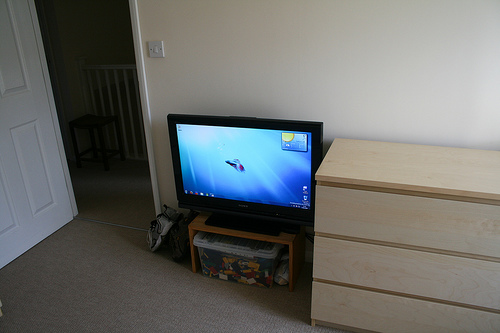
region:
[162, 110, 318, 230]
a flat screen tv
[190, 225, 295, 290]
container full of legos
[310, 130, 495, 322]
a tan three drawer dresser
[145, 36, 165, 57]
a white light switch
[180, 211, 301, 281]
a wood tv stand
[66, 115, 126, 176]
a little stool in hallway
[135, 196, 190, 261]
two pair of tennis shoes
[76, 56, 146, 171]
a white railing in hallway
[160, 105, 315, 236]
a tv with the screen on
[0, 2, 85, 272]
a white bedroom door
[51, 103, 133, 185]
small stole sitting outside the room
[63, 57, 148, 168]
Railing outside the room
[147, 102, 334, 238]
television that is switched on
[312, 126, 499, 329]
Dresser with three drawers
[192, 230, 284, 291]
Clear tote with white lid holding lego's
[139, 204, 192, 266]
Two pairs of shoes leaning against the stand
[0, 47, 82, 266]
A white door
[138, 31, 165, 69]
A light switch on the wall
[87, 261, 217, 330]
Light tan colored carpet of the room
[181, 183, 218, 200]
Six small icons on the television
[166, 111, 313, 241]
Computer sitting on stool.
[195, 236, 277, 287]
Plastic bin under stool.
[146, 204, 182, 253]
Shoes on floor next to stool.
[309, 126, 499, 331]
A three drawer chest.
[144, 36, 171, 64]
Light switch on wall.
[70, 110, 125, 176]
A stool in hallway.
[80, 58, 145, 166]
Banister railing in hallway.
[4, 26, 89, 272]
A white door to room.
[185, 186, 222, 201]
Icons at bottom of computer.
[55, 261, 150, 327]
Carpet on room floor.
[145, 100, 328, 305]
Flat screen TV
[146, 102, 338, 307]
Flat screen TV on top of a small table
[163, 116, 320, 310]
TV is on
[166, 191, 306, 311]
Storage of toys under a small table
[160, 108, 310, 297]
A TV is on top of the wooden table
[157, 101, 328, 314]
A black TV against the wall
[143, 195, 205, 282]
Shoes next to the wooden table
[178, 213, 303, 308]
Small wooden table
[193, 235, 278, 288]
Storage container full of toys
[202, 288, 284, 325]
carpet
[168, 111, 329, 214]
A flat screen TV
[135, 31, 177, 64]
a light switch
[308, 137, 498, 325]
a multi drawer dresser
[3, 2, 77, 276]
a white painted door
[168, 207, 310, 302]
dark colored tv stand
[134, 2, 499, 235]
white painted wall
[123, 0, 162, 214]
right half of door frame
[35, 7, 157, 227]
dark door way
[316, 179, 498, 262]
large dresser drawer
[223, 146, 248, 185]
image on flat screen